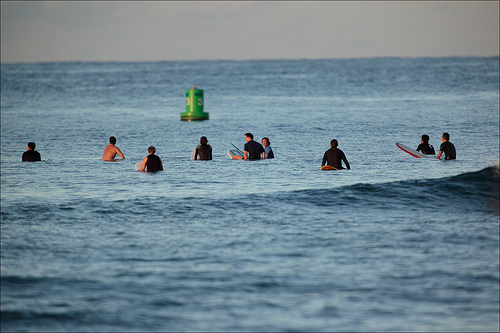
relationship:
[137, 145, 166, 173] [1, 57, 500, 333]
person in water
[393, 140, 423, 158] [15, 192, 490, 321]
surfboard poking out of water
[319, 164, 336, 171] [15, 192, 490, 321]
surfboard poking out of water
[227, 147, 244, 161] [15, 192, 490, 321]
surfboard poking out of water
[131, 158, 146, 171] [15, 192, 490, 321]
surfboard poking out of water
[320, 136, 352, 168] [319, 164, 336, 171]
person on surfboard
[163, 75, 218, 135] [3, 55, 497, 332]
buoy in ocean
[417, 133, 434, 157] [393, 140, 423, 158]
man on surfboard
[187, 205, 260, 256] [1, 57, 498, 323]
ripples in water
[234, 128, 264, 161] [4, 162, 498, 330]
person in water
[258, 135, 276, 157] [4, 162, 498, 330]
woman in water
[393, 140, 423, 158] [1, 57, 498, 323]
surfboard sticking out of water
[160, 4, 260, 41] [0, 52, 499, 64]
sky above horizon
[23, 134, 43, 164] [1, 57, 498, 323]
man in water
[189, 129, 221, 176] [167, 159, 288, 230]
man in water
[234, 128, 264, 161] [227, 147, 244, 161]
person laying on surfboard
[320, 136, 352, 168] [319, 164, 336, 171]
person sitting on surfboard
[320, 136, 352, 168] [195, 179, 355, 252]
person on water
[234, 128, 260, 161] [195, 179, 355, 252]
person on water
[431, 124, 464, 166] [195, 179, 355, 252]
person on water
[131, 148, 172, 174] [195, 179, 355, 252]
person on water